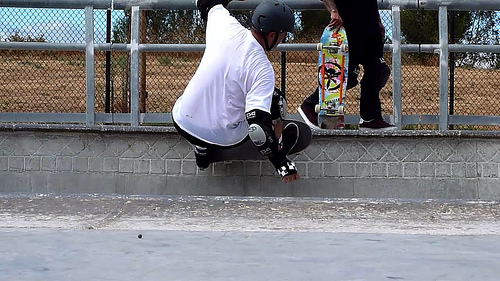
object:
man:
[172, 0, 301, 183]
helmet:
[252, 0, 295, 51]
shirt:
[172, 4, 275, 146]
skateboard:
[209, 119, 312, 164]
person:
[297, 0, 391, 131]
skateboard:
[314, 24, 349, 129]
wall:
[0, 122, 500, 200]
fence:
[0, 7, 500, 131]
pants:
[304, 29, 384, 118]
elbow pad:
[245, 109, 279, 156]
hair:
[250, 26, 271, 38]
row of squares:
[0, 156, 500, 178]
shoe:
[281, 122, 302, 156]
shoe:
[196, 156, 210, 171]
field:
[1, 56, 500, 130]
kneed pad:
[359, 57, 390, 90]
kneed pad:
[346, 64, 360, 89]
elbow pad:
[196, 0, 233, 22]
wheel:
[317, 42, 324, 50]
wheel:
[340, 44, 347, 53]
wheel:
[315, 104, 322, 113]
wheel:
[337, 105, 344, 113]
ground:
[1, 227, 500, 280]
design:
[0, 133, 500, 177]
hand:
[328, 13, 343, 34]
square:
[483, 162, 499, 177]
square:
[466, 162, 482, 178]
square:
[451, 162, 467, 178]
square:
[419, 162, 436, 177]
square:
[403, 162, 420, 177]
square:
[387, 162, 404, 177]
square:
[370, 162, 388, 177]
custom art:
[318, 25, 349, 129]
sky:
[0, 6, 500, 68]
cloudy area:
[0, 21, 106, 44]